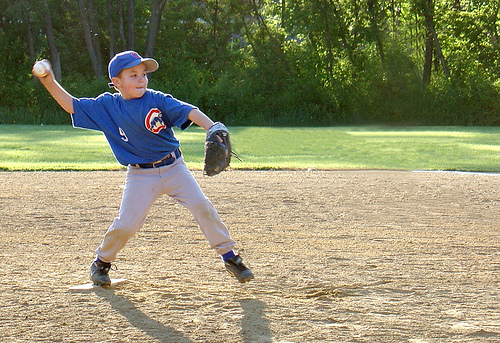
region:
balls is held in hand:
[29, 57, 56, 80]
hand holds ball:
[32, 59, 54, 81]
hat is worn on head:
[108, 49, 160, 81]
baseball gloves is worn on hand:
[200, 120, 236, 178]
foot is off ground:
[216, 248, 256, 284]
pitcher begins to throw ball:
[32, 49, 253, 291]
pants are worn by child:
[97, 150, 239, 264]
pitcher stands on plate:
[30, 49, 257, 287]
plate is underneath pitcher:
[68, 274, 129, 294]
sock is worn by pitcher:
[219, 248, 239, 260]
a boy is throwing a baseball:
[28, 47, 259, 292]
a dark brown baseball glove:
[204, 121, 231, 176]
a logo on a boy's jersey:
[144, 108, 166, 135]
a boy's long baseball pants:
[96, 162, 236, 264]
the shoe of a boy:
[86, 258, 112, 289]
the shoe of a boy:
[221, 256, 254, 283]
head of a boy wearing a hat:
[104, 49, 158, 99]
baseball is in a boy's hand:
[31, 58, 51, 79]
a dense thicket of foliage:
[1, 1, 498, 127]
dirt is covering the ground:
[0, 166, 498, 342]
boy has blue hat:
[103, 54, 156, 82]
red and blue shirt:
[98, 83, 156, 172]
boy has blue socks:
[228, 241, 241, 263]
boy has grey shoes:
[235, 242, 269, 291]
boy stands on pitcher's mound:
[66, 246, 128, 309]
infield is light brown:
[280, 202, 395, 302]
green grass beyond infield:
[262, 131, 412, 171]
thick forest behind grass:
[103, 1, 450, 134]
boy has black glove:
[185, 106, 238, 164]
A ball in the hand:
[35, 60, 47, 75]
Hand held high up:
[44, 77, 54, 86]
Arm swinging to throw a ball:
[60, 93, 68, 105]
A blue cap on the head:
[118, 52, 138, 65]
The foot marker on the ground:
[72, 283, 92, 289]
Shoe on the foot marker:
[90, 267, 110, 283]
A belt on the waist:
[160, 161, 170, 163]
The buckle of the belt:
[152, 161, 161, 165]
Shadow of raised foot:
[242, 300, 260, 313]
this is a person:
[26, 45, 255, 300]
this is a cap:
[108, 47, 157, 72]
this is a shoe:
[89, 257, 116, 287]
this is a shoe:
[223, 249, 254, 281]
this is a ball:
[33, 60, 51, 76]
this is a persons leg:
[165, 177, 254, 285]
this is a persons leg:
[90, 155, 157, 288]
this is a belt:
[128, 150, 183, 170]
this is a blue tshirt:
[73, 90, 194, 160]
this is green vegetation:
[275, 5, 495, 117]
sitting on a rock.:
[247, 216, 257, 243]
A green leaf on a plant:
[260, 65, 262, 67]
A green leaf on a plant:
[276, 70, 279, 73]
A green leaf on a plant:
[325, 63, 330, 67]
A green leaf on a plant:
[403, 77, 410, 84]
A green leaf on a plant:
[440, 88, 442, 90]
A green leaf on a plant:
[465, 89, 471, 97]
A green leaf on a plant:
[371, 105, 374, 107]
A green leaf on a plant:
[308, 105, 315, 107]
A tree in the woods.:
[418, 7, 463, 115]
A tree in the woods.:
[358, 18, 404, 116]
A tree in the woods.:
[296, 22, 348, 143]